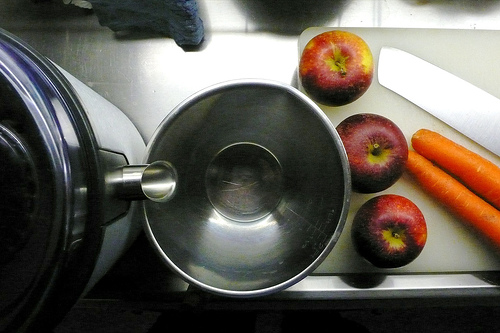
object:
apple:
[331, 113, 406, 193]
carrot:
[406, 148, 499, 241]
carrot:
[411, 127, 499, 195]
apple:
[352, 194, 428, 268]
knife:
[374, 45, 500, 155]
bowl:
[130, 77, 357, 304]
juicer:
[3, 30, 158, 317]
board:
[295, 23, 500, 275]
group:
[297, 28, 428, 269]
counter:
[2, 1, 500, 289]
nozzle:
[103, 148, 177, 219]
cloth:
[92, 2, 213, 52]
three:
[299, 29, 434, 262]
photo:
[0, 1, 498, 330]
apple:
[299, 29, 372, 106]